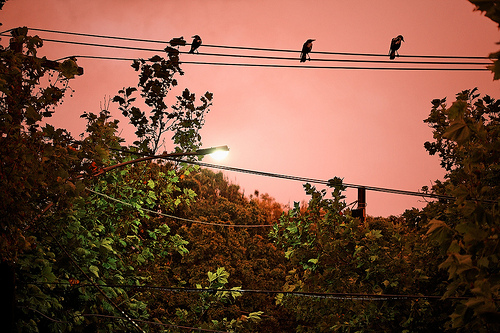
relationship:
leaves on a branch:
[167, 85, 208, 133] [51, 188, 123, 265]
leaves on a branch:
[194, 268, 266, 315] [117, 144, 209, 165]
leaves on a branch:
[267, 204, 319, 259] [154, 118, 171, 147]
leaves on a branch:
[187, 86, 215, 115] [275, 232, 333, 304]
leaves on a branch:
[109, 33, 194, 158] [110, 33, 197, 156]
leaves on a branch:
[5, 43, 499, 321] [94, 142, 239, 173]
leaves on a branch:
[110, 37, 206, 145] [80, 147, 225, 178]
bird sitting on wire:
[293, 27, 317, 62] [212, 44, 294, 69]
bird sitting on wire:
[298, 38, 317, 64] [255, 45, 287, 70]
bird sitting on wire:
[388, 33, 405, 60] [427, 55, 475, 75]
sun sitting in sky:
[206, 142, 235, 165] [0, 0, 499, 217]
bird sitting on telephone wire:
[298, 38, 317, 64] [2, 15, 497, 86]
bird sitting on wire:
[388, 33, 405, 60] [15, 16, 493, 85]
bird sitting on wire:
[298, 38, 317, 64] [15, 16, 493, 85]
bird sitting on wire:
[186, 26, 203, 55] [15, 16, 493, 85]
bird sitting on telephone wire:
[388, 33, 405, 60] [2, 25, 497, 73]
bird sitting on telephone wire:
[298, 38, 317, 64] [2, 25, 497, 73]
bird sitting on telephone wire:
[188, 33, 203, 56] [2, 25, 497, 73]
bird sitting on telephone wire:
[298, 38, 317, 64] [333, 49, 445, 76]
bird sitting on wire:
[298, 38, 317, 64] [222, 25, 499, 85]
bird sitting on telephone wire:
[298, 38, 317, 64] [3, 15, 482, 60]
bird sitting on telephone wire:
[298, 38, 317, 64] [1, 35, 498, 65]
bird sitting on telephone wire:
[388, 33, 405, 60] [20, 278, 472, 303]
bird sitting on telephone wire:
[188, 33, 203, 56] [51, 32, 498, 67]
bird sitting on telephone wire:
[298, 38, 317, 64] [20, 278, 472, 303]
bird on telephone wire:
[298, 38, 317, 64] [3, 27, 496, 74]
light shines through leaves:
[187, 145, 240, 167] [202, 259, 251, 300]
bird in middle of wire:
[388, 33, 405, 60] [27, 49, 488, 69]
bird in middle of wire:
[298, 38, 317, 64] [27, 49, 488, 69]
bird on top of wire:
[298, 38, 317, 64] [2, 22, 499, 59]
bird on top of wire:
[389, 32, 404, 60] [2, 32, 491, 66]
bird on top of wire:
[188, 33, 203, 56] [2, 22, 499, 59]